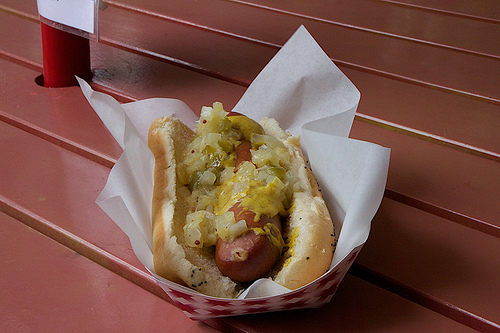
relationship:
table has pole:
[12, 7, 491, 326] [40, 0, 102, 87]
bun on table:
[143, 101, 335, 301] [12, 7, 491, 326]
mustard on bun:
[232, 114, 261, 134] [143, 101, 335, 301]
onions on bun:
[190, 102, 228, 239] [143, 101, 335, 301]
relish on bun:
[227, 144, 240, 164] [143, 101, 335, 301]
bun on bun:
[150, 116, 335, 292] [143, 101, 335, 301]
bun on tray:
[143, 101, 335, 301] [134, 243, 358, 314]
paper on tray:
[235, 22, 356, 127] [134, 243, 358, 314]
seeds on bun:
[182, 266, 216, 291] [150, 116, 335, 292]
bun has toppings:
[143, 101, 335, 301] [182, 112, 291, 247]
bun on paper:
[143, 101, 335, 301] [235, 22, 356, 127]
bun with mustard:
[143, 101, 335, 301] [232, 114, 261, 134]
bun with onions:
[143, 101, 335, 301] [190, 102, 228, 239]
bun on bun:
[143, 101, 335, 301] [150, 116, 335, 292]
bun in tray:
[143, 101, 335, 301] [134, 243, 358, 314]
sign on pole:
[32, 0, 103, 44] [40, 0, 102, 87]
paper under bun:
[235, 22, 356, 127] [143, 101, 335, 301]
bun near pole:
[143, 101, 335, 301] [40, 0, 102, 87]